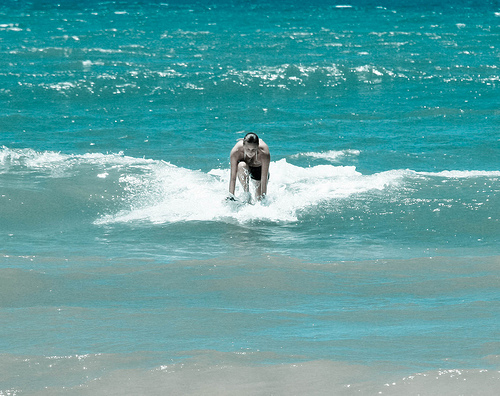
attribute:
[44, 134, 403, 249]
wave — white, small, blue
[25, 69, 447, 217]
water — green, white, splashing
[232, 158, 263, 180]
knee — bent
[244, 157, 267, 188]
pants — black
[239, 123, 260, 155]
hair — slicked, dark, here, black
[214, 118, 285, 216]
surfer — squatting, young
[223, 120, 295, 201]
person — shirtless, hunched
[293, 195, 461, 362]
ocean — here, white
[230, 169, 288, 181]
shorts — black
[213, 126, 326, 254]
lady — kneeling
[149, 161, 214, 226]
splash — white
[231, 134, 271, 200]
woman — here, surfing